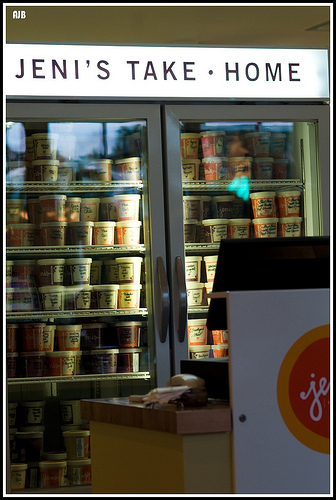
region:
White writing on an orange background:
[300, 369, 331, 423]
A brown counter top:
[85, 403, 230, 428]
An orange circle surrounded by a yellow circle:
[264, 307, 335, 459]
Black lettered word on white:
[221, 59, 302, 83]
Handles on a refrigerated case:
[151, 252, 191, 352]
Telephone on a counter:
[163, 372, 209, 405]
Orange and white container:
[188, 317, 207, 343]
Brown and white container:
[202, 215, 227, 243]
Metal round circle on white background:
[235, 407, 250, 430]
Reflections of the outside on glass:
[56, 125, 142, 164]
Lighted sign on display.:
[17, 38, 206, 98]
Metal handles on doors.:
[137, 246, 193, 345]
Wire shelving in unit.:
[23, 361, 115, 394]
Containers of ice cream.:
[46, 317, 91, 381]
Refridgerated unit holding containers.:
[108, 68, 239, 374]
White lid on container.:
[90, 275, 127, 299]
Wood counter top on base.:
[73, 385, 147, 442]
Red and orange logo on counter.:
[267, 316, 327, 455]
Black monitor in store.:
[201, 234, 309, 333]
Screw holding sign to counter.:
[229, 404, 260, 439]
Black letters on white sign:
[14, 55, 299, 80]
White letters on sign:
[296, 372, 327, 420]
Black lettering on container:
[75, 264, 84, 276]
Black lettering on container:
[37, 140, 45, 152]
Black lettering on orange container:
[255, 197, 269, 209]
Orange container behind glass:
[36, 192, 66, 217]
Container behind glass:
[198, 128, 225, 154]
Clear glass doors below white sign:
[5, 40, 335, 498]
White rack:
[6, 176, 306, 191]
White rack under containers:
[5, 131, 303, 187]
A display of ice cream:
[5, 121, 318, 489]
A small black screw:
[234, 406, 258, 428]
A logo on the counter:
[272, 326, 335, 455]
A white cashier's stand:
[235, 289, 314, 480]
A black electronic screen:
[214, 232, 324, 313]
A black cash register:
[175, 349, 238, 394]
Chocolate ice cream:
[119, 320, 141, 348]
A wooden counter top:
[81, 400, 233, 443]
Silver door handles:
[145, 257, 199, 345]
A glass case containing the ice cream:
[2, 130, 146, 382]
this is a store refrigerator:
[2, 96, 321, 489]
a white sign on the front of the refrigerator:
[2, 48, 322, 98]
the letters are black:
[9, 47, 301, 82]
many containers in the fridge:
[7, 135, 139, 372]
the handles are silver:
[145, 250, 190, 348]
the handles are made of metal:
[131, 230, 196, 351]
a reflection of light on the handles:
[149, 280, 194, 308]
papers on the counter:
[138, 379, 193, 409]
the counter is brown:
[86, 394, 218, 435]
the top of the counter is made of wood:
[79, 389, 223, 434]